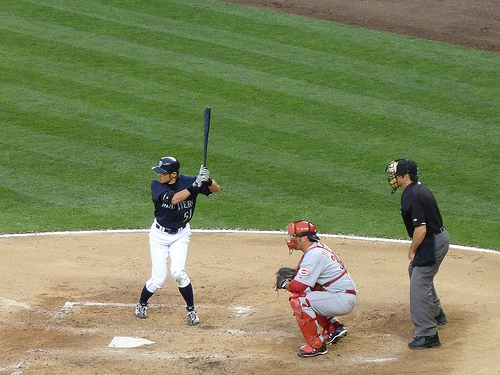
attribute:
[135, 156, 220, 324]
batter — ready, batting, waiting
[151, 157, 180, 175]
helmet — black, blue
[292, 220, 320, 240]
helmet — red, orange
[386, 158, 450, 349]
umpire — standing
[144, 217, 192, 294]
pants — white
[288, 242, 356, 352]
uniform — gray, red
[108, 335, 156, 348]
plate — white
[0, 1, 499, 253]
field — green, grass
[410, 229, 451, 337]
pants — gray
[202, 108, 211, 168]
bat — here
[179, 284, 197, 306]
sock — long, blue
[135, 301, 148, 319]
shoe — white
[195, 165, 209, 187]
gloves — white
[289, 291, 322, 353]
pad — red, orange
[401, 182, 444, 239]
shirt — black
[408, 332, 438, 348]
shoe — black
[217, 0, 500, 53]
dirt — brown